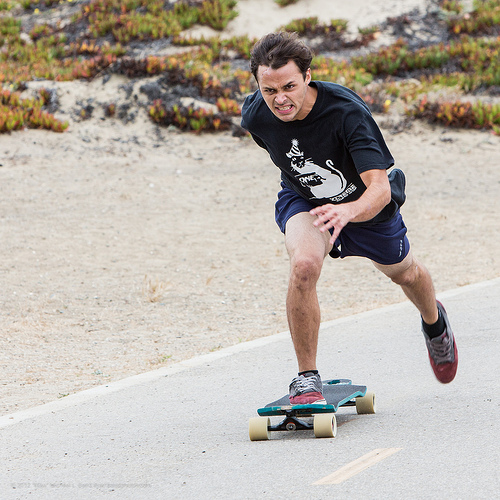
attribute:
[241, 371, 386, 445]
board — green, blue, black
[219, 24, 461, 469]
man — gritting, brunette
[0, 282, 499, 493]
road — brown, painted, lined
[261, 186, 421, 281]
shorts — blue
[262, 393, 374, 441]
tires — yellow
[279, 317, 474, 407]
shoes — gray, red